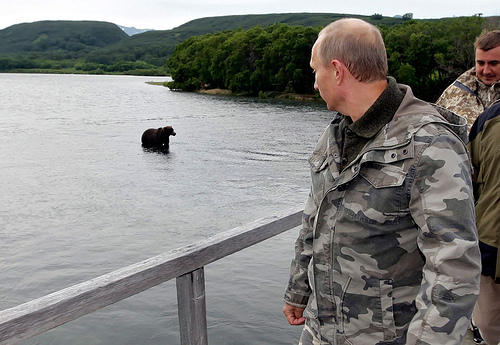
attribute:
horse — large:
[145, 112, 200, 153]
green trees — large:
[1, 13, 499, 104]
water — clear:
[36, 139, 146, 258]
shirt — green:
[331, 96, 404, 153]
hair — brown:
[472, 27, 499, 51]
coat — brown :
[438, 72, 498, 134]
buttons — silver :
[328, 147, 411, 169]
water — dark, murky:
[2, 72, 337, 343]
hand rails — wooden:
[3, 201, 308, 343]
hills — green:
[160, 11, 318, 82]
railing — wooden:
[8, 202, 305, 344]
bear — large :
[139, 125, 177, 157]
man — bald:
[288, 34, 481, 341]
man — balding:
[280, 15, 479, 344]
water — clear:
[94, 160, 200, 230]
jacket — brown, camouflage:
[442, 67, 484, 117]